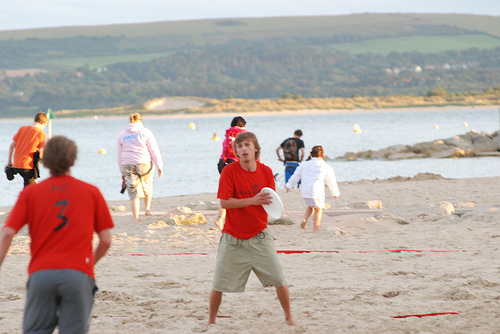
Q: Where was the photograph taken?
A: A beach.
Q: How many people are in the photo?
A: Seven.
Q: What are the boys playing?
A: Frisbee.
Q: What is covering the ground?
A: Sand.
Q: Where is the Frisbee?
A: In the boy's hands.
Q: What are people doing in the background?
A: Walking.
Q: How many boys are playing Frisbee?
A: Two.